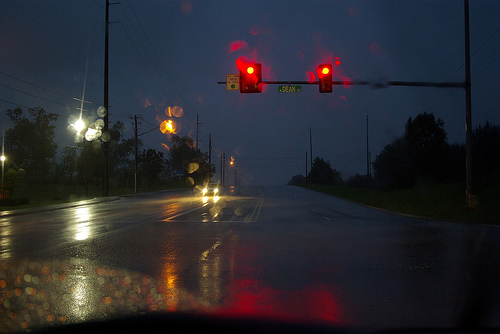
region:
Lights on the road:
[207, 44, 372, 99]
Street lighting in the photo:
[202, 37, 405, 113]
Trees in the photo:
[371, 119, 438, 184]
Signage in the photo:
[273, 67, 312, 97]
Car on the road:
[191, 174, 226, 200]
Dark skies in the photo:
[148, 38, 208, 80]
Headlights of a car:
[194, 180, 226, 194]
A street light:
[155, 99, 185, 146]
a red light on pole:
[243, 62, 259, 77]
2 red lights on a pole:
[222, 59, 349, 91]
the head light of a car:
[197, 187, 209, 197]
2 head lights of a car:
[200, 188, 220, 194]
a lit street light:
[71, 115, 88, 133]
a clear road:
[226, 178, 321, 332]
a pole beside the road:
[461, 50, 473, 167]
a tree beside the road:
[398, 115, 442, 186]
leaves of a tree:
[4, 108, 26, 123]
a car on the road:
[199, 181, 221, 195]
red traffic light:
[195, 32, 475, 149]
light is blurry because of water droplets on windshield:
[225, 37, 351, 93]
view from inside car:
[6, 3, 496, 326]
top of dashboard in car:
[6, 312, 344, 328]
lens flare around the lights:
[55, 92, 253, 217]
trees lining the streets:
[290, 101, 490, 224]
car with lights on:
[195, 175, 230, 196]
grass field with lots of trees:
[0, 77, 162, 202]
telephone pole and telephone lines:
[15, 1, 197, 192]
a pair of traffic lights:
[218, 45, 345, 98]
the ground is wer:
[20, 163, 427, 296]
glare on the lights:
[50, 85, 118, 147]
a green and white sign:
[269, 78, 307, 97]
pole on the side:
[442, 3, 499, 220]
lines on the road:
[233, 168, 273, 228]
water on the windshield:
[11, 225, 198, 322]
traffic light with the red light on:
[317, 61, 332, 93]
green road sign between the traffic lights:
[276, 83, 301, 95]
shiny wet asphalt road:
[0, 179, 499, 332]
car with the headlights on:
[200, 179, 225, 196]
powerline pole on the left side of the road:
[100, 0, 117, 197]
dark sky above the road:
[0, 0, 495, 180]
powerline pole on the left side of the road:
[125, 110, 145, 190]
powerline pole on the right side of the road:
[360, 107, 376, 193]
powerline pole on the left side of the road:
[306, 124, 317, 170]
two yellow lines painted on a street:
[246, 190, 272, 232]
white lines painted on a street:
[286, 182, 341, 226]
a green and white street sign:
[275, 82, 301, 94]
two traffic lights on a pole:
[236, 60, 354, 100]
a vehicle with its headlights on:
[198, 186, 222, 198]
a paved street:
[124, 205, 356, 254]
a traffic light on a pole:
[315, 56, 334, 95]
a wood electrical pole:
[305, 120, 317, 179]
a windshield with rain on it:
[0, 246, 274, 321]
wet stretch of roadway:
[1, 170, 491, 325]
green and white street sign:
[276, 80, 306, 94]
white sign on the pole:
[223, 70, 240, 95]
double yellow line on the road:
[245, 182, 270, 231]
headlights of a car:
[203, 186, 218, 193]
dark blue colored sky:
[0, 1, 499, 193]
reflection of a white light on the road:
[66, 197, 103, 319]